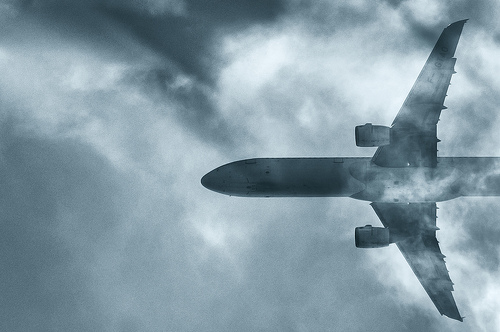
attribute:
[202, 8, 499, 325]
plane — flying, long, large, dark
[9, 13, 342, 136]
sky — dark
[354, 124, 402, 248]
engines — small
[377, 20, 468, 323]
wings — angled back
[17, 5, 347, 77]
cloud — dark, grey